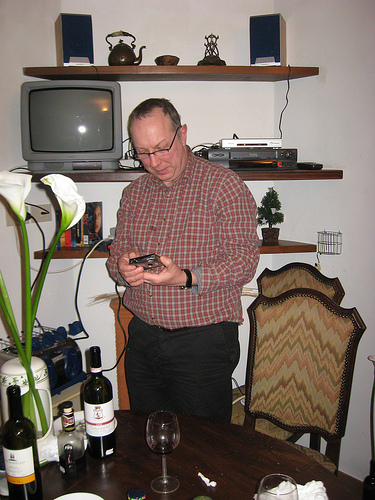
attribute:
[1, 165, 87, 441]
plant — white, large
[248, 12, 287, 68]
speaker — black and silver 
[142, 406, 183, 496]
glass —  clear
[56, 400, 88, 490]
bottle —  mostly empty,  small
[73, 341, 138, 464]
wine — red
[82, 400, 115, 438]
label —  red and white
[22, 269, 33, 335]
stem —  green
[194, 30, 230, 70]
statue —  bronze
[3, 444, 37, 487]
label —  white and orange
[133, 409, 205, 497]
wine — red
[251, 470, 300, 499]
glass —  The top,  clear, for wine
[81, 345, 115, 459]
bottle — for wine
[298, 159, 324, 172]
remote —  black, for tv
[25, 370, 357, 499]
table —  dark,  with rounded edge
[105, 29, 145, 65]
teapot —  small,  antique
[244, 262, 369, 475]
chairs — with static design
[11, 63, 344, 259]
shelves — set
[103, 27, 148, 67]
kettle — small, metal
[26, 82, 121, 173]
tv —  small,  grey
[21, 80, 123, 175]
television —  small,  grey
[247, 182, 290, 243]
item —  decorative,  small,  holiday themed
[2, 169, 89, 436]
calla lillies —  tall 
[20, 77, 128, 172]
tv — grey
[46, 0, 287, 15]
corner —  oddly shaped